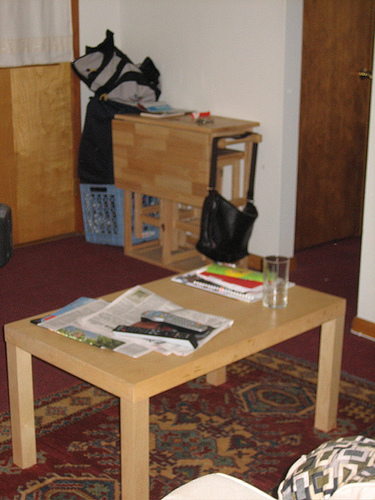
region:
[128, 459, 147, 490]
the table is wooden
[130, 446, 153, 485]
the table is wooden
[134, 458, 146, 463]
the table is wooden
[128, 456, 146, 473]
the table is wooden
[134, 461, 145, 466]
the table is wooden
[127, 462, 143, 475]
the table is wooden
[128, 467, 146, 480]
the table is wooden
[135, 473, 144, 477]
the table is wooden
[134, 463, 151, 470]
the table is wooden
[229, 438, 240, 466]
the carpet is red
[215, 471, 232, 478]
the carpet is red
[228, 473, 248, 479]
the carpet is red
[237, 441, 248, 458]
the carpet is red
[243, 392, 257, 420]
the carpet is red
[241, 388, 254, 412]
the carpet is red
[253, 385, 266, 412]
the carpet is red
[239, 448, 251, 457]
the carpet is red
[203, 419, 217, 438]
the carpet is red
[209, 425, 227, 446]
the carpet is red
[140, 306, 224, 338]
Remote control lying on coffee table.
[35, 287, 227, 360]
News paper lying on coffee table.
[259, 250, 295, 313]
Empty glass sitting on coffee table.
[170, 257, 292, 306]
Books lying on coffee table.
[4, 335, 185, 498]
Two legs of blond colored coffee table.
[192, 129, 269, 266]
Black purse hanging on edge of table.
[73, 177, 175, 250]
Blue clothes basket in corner.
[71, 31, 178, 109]
Gray and black grip bag sitting in corner.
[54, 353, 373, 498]
Persian style accent rug under coffee table.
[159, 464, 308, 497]
Edge of chair arm.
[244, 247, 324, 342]
a glass on the table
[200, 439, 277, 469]
a patterned rug in red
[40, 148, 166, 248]
the blue milk crate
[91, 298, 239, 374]
remotes on top of a newspaper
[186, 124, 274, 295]
a black leather purse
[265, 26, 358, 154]
the doorway is wood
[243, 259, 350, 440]
the table is wood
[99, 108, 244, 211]
this table folds up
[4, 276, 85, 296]
the carpet is red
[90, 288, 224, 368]
the right remote is silver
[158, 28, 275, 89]
The wall is white.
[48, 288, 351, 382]
The table is wood.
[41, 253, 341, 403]
The table is tan.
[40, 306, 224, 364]
The papers are on the table.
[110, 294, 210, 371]
Two remotes are on the table.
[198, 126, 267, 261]
The purse is black.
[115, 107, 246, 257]
the TV tray is tan.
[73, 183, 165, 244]
The laundry basket is blue.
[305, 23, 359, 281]
The door is brown.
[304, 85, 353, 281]
The door is wood.